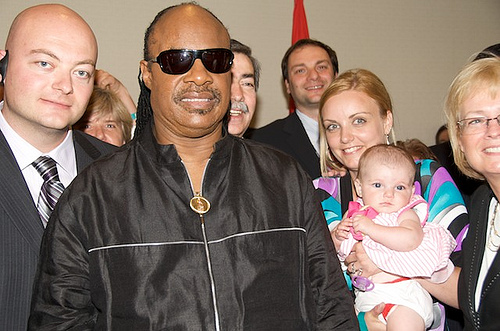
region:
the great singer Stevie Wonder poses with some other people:
[25, 1, 365, 329]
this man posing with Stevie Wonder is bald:
[2, 2, 100, 132]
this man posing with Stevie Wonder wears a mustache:
[229, 31, 264, 138]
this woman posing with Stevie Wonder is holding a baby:
[314, 66, 465, 327]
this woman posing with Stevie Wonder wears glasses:
[444, 54, 499, 329]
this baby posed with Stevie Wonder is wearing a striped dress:
[333, 140, 458, 326]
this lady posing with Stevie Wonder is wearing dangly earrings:
[313, 67, 399, 174]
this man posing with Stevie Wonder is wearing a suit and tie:
[1, 0, 124, 329]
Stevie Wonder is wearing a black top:
[27, 125, 364, 329]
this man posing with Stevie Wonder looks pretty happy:
[252, 35, 344, 185]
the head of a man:
[1, 4, 106, 135]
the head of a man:
[279, 37, 341, 104]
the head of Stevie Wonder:
[130, 0, 245, 149]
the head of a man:
[231, 34, 259, 136]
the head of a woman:
[315, 68, 399, 172]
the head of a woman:
[444, 55, 498, 179]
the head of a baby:
[352, 140, 417, 214]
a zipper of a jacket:
[191, 192, 227, 329]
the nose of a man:
[51, 70, 79, 97]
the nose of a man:
[180, 65, 219, 89]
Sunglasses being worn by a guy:
[141, 48, 236, 78]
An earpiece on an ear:
[0, 48, 7, 80]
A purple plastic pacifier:
[350, 275, 373, 292]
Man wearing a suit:
[246, 38, 339, 170]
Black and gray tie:
[30, 157, 65, 225]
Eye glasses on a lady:
[455, 115, 498, 136]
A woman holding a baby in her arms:
[303, 68, 471, 329]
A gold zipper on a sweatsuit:
[189, 193, 209, 213]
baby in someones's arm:
[327, 141, 459, 329]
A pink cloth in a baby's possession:
[345, 200, 378, 240]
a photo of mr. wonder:
[1, 0, 498, 330]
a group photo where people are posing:
[1, 2, 498, 329]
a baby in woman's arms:
[290, 61, 478, 330]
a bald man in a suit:
[0, 1, 142, 330]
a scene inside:
[2, 0, 498, 324]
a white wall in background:
[0, 0, 499, 178]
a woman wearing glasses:
[438, 44, 498, 327]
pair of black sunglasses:
[139, 39, 240, 85]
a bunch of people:
[1, 1, 498, 325]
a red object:
[277, 0, 329, 73]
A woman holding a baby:
[306, 64, 469, 329]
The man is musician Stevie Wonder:
[27, 3, 362, 327]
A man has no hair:
[1, 2, 100, 135]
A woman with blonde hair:
[442, 51, 498, 184]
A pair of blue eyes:
[318, 115, 371, 134]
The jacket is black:
[22, 121, 363, 328]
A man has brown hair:
[279, 33, 342, 111]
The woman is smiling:
[310, 66, 400, 168]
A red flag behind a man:
[286, 1, 318, 115]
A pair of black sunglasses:
[141, 44, 236, 79]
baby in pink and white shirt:
[332, 148, 459, 330]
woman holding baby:
[300, 66, 467, 324]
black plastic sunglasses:
[146, 40, 238, 74]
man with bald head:
[3, 13, 120, 307]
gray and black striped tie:
[23, 147, 66, 223]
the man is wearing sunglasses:
[150, 49, 236, 75]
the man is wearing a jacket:
[34, 133, 362, 329]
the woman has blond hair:
[447, 57, 498, 182]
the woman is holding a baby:
[307, 68, 467, 328]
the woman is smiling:
[341, 141, 363, 156]